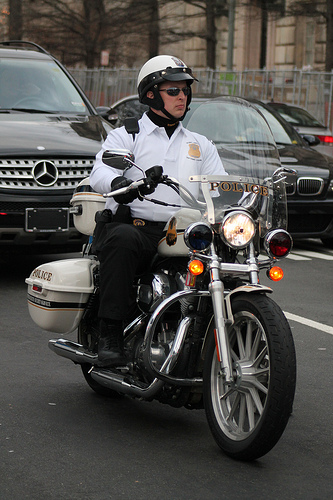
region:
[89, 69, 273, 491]
a man riding a motorcycle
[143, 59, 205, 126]
a man wearing sunglasses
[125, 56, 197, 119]
a man wearing a helmet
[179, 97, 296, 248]
a windshield on a motorcycle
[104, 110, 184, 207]
a man wearing gloves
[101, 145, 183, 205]
a man wearing black gloves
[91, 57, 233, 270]
a man wearing a police uniform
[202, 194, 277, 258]
the headlight on a motorcycle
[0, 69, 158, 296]
a black car behind a motorcycle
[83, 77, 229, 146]
a man wearing a black turtle neck shirt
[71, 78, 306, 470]
The police officer rides a motorcycle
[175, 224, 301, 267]
headlight on front of motorcycle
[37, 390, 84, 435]
Gum on the pavement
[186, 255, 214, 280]
Orange light on the front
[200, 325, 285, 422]
silver hubcap on the wheel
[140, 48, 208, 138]
Police officer wearing a helmet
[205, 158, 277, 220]
Police decal on windshield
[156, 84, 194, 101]
Sunglasses on the man's face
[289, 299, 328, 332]
White paint on the pavement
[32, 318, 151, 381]
Police man has foot on foot rest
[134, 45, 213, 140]
a man wearing a helmet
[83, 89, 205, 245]
a man wearing gloves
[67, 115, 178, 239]
a man wearing black gloves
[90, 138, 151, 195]
rear view mirror on a motorcyle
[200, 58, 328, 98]
a tall chain link fence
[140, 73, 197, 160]
a man wearing a white shirt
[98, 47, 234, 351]
police officer in black pants and white shirt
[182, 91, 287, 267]
clear windshield of motorcycle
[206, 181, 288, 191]
black and yellow police emblem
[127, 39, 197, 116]
black and white helmet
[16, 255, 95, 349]
white tank with police emblem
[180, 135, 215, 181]
embroidered badge on shirt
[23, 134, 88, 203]
mercedes emblem on car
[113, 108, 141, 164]
officer's radio on shoulder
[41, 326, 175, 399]
chrome mufflers on bike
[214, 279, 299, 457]
front silver and black wheel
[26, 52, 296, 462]
police officer on a motorcycle riding through traffic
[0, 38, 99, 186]
a black van driving behind the police officer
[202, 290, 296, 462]
front tire of a police motorcycle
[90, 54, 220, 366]
police officer wearing sunglasses and looking forward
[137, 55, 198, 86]
protective black and white helmet for a police officer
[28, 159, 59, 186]
Mercedes logo on a car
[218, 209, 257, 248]
bright yellow headlight of the motorcycle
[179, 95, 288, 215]
the motorcycle's clear glass windshield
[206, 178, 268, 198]
"POLICE" marked on the motorcycle windshield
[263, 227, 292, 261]
red emergency light on the front of the motorcycle